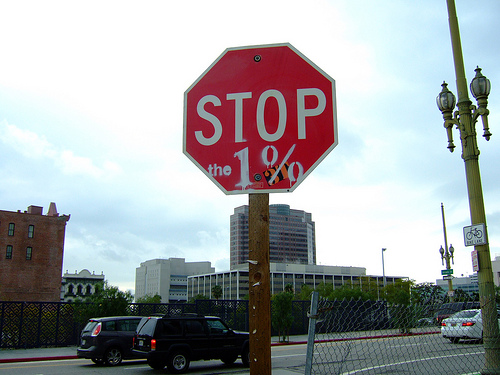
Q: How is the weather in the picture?
A: It is cloudy.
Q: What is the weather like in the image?
A: It is cloudy.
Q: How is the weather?
A: It is cloudy.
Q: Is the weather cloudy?
A: Yes, it is cloudy.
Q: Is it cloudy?
A: Yes, it is cloudy.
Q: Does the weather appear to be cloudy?
A: Yes, it is cloudy.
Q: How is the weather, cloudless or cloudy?
A: It is cloudy.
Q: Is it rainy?
A: No, it is cloudy.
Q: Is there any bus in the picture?
A: No, there are no buses.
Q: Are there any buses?
A: No, there are no buses.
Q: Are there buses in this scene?
A: No, there are no buses.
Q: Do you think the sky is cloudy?
A: Yes, the sky is cloudy.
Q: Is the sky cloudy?
A: Yes, the sky is cloudy.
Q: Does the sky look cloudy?
A: Yes, the sky is cloudy.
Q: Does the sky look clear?
A: No, the sky is cloudy.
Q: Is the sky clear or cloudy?
A: The sky is cloudy.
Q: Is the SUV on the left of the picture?
A: Yes, the SUV is on the left of the image.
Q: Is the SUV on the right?
A: No, the SUV is on the left of the image.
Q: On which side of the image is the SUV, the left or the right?
A: The SUV is on the left of the image.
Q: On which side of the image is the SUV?
A: The SUV is on the left of the image.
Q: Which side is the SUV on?
A: The SUV is on the left of the image.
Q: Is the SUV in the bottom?
A: Yes, the SUV is in the bottom of the image.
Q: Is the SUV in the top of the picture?
A: No, the SUV is in the bottom of the image.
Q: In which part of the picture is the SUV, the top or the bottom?
A: The SUV is in the bottom of the image.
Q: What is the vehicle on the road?
A: The vehicle is a SUV.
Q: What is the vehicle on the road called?
A: The vehicle is a SUV.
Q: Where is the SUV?
A: The SUV is on the road.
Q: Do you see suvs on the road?
A: Yes, there is a SUV on the road.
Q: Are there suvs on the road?
A: Yes, there is a SUV on the road.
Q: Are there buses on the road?
A: No, there is a SUV on the road.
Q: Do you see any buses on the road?
A: No, there is a SUV on the road.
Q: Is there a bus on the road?
A: No, there is a SUV on the road.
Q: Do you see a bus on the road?
A: No, there is a SUV on the road.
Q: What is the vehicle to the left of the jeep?
A: The vehicle is a SUV.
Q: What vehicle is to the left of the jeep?
A: The vehicle is a SUV.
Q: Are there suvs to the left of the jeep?
A: Yes, there is a SUV to the left of the jeep.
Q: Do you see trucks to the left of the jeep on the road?
A: No, there is a SUV to the left of the jeep.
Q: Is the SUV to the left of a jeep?
A: Yes, the SUV is to the left of a jeep.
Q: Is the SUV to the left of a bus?
A: No, the SUV is to the left of a jeep.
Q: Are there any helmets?
A: No, there are no helmets.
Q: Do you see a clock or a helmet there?
A: No, there are no helmets or clocks.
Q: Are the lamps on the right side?
A: Yes, the lamps are on the right of the image.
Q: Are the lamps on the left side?
A: No, the lamps are on the right of the image.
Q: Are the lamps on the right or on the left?
A: The lamps are on the right of the image.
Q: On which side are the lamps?
A: The lamps are on the right of the image.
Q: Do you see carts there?
A: No, there are no carts.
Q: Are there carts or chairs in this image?
A: No, there are no carts or chairs.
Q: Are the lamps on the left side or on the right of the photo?
A: The lamps are on the right of the image.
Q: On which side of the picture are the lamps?
A: The lamps are on the right of the image.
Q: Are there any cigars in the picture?
A: No, there are no cigars.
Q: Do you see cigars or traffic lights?
A: No, there are no cigars or traffic lights.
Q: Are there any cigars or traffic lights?
A: No, there are no cigars or traffic lights.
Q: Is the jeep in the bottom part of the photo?
A: Yes, the jeep is in the bottom of the image.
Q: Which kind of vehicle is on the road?
A: The vehicle is a jeep.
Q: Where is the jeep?
A: The jeep is on the road.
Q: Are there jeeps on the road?
A: Yes, there is a jeep on the road.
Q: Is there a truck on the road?
A: No, there is a jeep on the road.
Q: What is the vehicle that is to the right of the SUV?
A: The vehicle is a jeep.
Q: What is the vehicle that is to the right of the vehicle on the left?
A: The vehicle is a jeep.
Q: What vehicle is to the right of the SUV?
A: The vehicle is a jeep.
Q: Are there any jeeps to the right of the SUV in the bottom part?
A: Yes, there is a jeep to the right of the SUV.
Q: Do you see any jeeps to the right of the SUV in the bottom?
A: Yes, there is a jeep to the right of the SUV.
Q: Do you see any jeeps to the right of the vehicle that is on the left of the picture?
A: Yes, there is a jeep to the right of the SUV.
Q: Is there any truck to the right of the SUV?
A: No, there is a jeep to the right of the SUV.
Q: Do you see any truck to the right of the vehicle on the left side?
A: No, there is a jeep to the right of the SUV.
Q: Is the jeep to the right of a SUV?
A: Yes, the jeep is to the right of a SUV.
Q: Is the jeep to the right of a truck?
A: No, the jeep is to the right of a SUV.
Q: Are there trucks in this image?
A: No, there are no trucks.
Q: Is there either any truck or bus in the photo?
A: No, there are no trucks or buses.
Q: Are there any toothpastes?
A: No, there are no toothpastes.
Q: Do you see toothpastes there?
A: No, there are no toothpastes.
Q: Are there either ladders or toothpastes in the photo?
A: No, there are no toothpastes or ladders.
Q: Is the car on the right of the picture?
A: Yes, the car is on the right of the image.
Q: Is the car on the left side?
A: No, the car is on the right of the image.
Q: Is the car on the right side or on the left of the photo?
A: The car is on the right of the image.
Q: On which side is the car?
A: The car is on the right of the image.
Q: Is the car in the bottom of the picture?
A: Yes, the car is in the bottom of the image.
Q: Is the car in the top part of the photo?
A: No, the car is in the bottom of the image.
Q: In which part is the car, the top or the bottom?
A: The car is in the bottom of the image.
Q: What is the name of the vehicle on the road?
A: The vehicle is a car.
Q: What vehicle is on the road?
A: The vehicle is a car.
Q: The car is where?
A: The car is on the road.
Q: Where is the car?
A: The car is on the road.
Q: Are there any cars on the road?
A: Yes, there is a car on the road.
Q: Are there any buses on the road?
A: No, there is a car on the road.